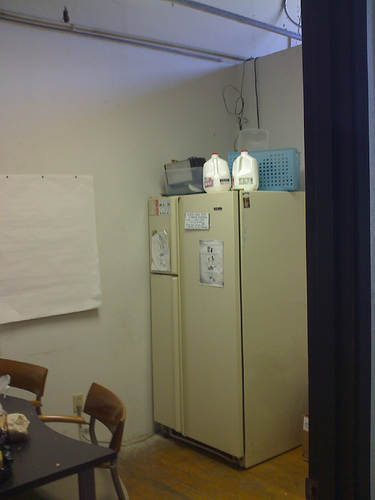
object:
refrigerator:
[176, 186, 309, 470]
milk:
[202, 152, 232, 194]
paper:
[198, 239, 225, 289]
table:
[0, 390, 119, 499]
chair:
[81, 380, 127, 500]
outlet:
[72, 393, 85, 415]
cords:
[253, 55, 260, 129]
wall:
[229, 43, 303, 191]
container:
[231, 149, 260, 192]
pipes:
[174, 0, 302, 43]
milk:
[232, 148, 260, 190]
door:
[177, 189, 244, 460]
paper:
[149, 228, 170, 272]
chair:
[0, 357, 49, 416]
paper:
[0, 169, 104, 325]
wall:
[0, 0, 235, 449]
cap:
[241, 149, 248, 153]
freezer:
[147, 195, 182, 435]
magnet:
[243, 192, 252, 210]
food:
[3, 409, 31, 444]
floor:
[98, 430, 309, 500]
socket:
[72, 392, 85, 413]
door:
[148, 196, 179, 277]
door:
[149, 273, 181, 434]